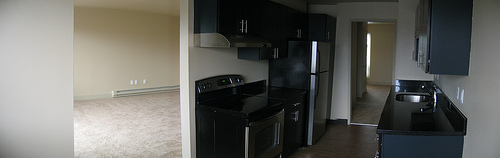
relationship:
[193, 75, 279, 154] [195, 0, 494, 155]
black stove in kitchen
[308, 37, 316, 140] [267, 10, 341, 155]
handles on refrigerator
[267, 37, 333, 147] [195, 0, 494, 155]
fridge in kitchen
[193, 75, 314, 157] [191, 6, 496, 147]
black stove in kitchen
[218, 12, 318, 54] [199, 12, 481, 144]
cabinets in kitchen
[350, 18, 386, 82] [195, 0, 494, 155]
doorway in kitchen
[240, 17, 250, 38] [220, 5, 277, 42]
handles on cabinet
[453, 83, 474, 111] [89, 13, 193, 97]
outlet on wall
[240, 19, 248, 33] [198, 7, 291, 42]
handles on doors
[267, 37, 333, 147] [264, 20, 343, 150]
fridge has handles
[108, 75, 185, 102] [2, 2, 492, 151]
baseboard in room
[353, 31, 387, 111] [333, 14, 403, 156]
hallway next rooms